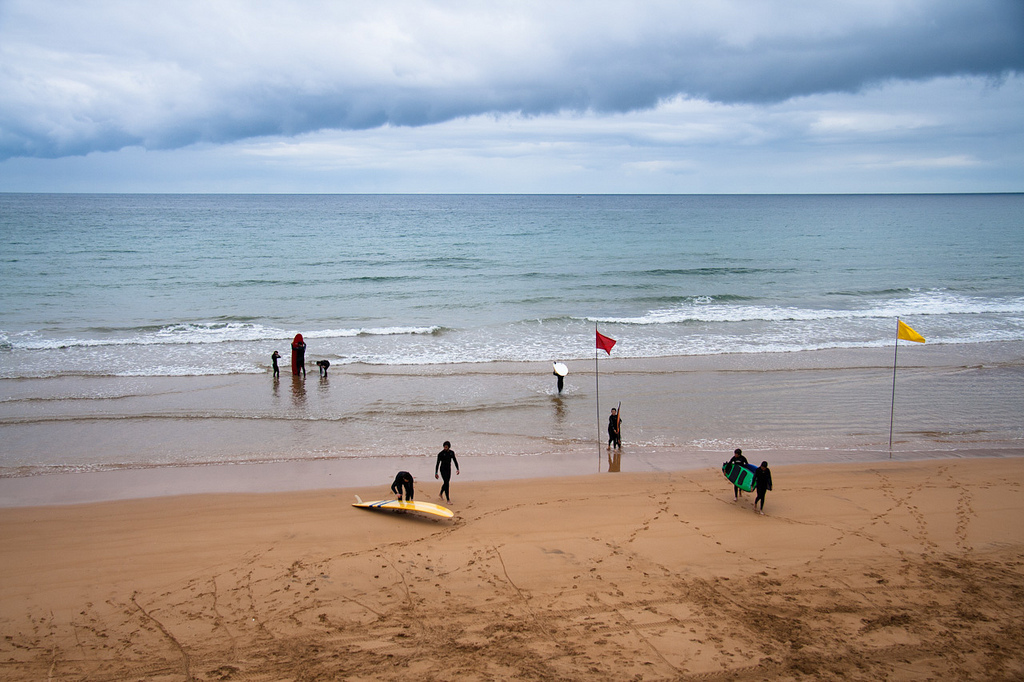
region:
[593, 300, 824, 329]
The waves are rushing.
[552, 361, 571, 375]
A white base of surfboard.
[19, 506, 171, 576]
A smooth surface of brown sand.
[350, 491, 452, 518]
A yellow surfboard with blue stripes.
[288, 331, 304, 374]
A tall and red surfboard.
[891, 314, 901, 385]
A small and thin pole.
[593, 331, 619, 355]
A red and small flag.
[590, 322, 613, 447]
the red flag on the pole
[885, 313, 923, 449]
the yellow flag on the pole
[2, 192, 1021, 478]
the large body of water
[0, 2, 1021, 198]
the clouds in the sky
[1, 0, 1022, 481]
the clouds above the water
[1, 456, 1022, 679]
the sand is brown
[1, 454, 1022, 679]
the tracks in the sand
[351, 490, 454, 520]
the surfboard is long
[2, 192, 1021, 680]
the people at the beach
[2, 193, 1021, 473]
the small waves in the water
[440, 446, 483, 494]
a perosn on the beach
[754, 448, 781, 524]
a perosn on the beach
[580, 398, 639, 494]
a perosn on the beach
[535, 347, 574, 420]
a perosn on the beach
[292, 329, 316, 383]
a perosn on the beach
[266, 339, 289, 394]
a perosn on the beach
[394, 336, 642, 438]
a body of water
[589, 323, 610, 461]
the flag is red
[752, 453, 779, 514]
A person is standing up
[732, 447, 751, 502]
A person is standing up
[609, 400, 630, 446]
A person is standing up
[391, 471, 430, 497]
A person is standing up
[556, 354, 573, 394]
A person is standing up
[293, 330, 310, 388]
A person is standing up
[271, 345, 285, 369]
A person is standing up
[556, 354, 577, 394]
A person is playing.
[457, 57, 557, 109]
a white fluffy cloud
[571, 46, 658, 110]
a white fluffy cloud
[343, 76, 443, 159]
a white fluffy cloud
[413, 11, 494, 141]
a white fluffy cloud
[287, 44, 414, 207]
a white fluffy cloud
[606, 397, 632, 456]
A person is standing up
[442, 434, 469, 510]
A person is standing up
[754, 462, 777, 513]
A person is standing up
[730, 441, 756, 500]
A person is standing up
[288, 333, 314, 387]
A person is standing up